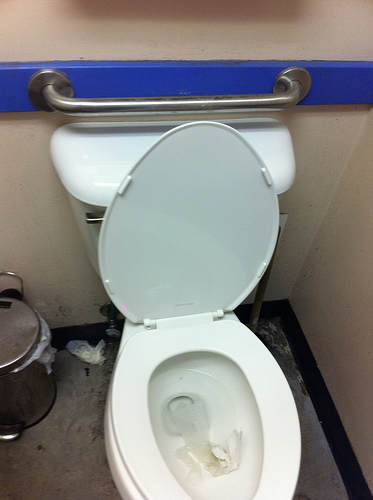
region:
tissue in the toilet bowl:
[179, 410, 239, 476]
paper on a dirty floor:
[64, 332, 109, 368]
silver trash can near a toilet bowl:
[1, 305, 63, 435]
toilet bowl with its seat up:
[74, 146, 288, 480]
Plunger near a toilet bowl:
[244, 222, 286, 343]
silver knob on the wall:
[96, 306, 123, 343]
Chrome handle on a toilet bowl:
[74, 205, 127, 232]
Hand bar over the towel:
[23, 62, 318, 121]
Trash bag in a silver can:
[29, 316, 62, 374]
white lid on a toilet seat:
[70, 122, 306, 320]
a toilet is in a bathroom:
[6, 8, 364, 498]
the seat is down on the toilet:
[110, 318, 301, 498]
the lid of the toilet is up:
[94, 120, 280, 326]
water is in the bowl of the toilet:
[150, 367, 236, 471]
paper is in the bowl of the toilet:
[172, 399, 249, 483]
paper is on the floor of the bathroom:
[63, 336, 107, 369]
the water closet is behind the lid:
[48, 116, 297, 308]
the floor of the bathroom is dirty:
[7, 263, 369, 497]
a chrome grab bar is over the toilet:
[26, 64, 311, 119]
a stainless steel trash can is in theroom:
[0, 287, 60, 436]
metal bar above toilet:
[34, 73, 310, 110]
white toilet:
[50, 129, 302, 499]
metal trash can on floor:
[1, 275, 53, 442]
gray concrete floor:
[3, 314, 348, 498]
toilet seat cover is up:
[97, 129, 279, 321]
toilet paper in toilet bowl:
[173, 413, 244, 475]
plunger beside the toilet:
[247, 223, 281, 339]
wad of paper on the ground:
[67, 339, 105, 364]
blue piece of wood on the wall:
[1, 61, 371, 110]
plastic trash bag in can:
[12, 306, 56, 373]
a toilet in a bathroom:
[9, 11, 362, 490]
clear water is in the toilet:
[150, 369, 232, 464]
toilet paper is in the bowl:
[176, 412, 246, 482]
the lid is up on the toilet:
[97, 120, 279, 318]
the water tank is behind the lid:
[49, 116, 298, 306]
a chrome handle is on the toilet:
[80, 209, 109, 227]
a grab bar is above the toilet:
[24, 62, 311, 122]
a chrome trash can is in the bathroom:
[0, 295, 59, 442]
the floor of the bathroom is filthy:
[47, 312, 356, 498]